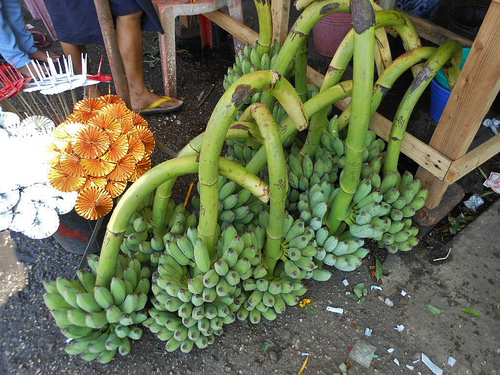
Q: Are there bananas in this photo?
A: Yes, there is a banana.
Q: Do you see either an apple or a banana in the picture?
A: Yes, there is a banana.